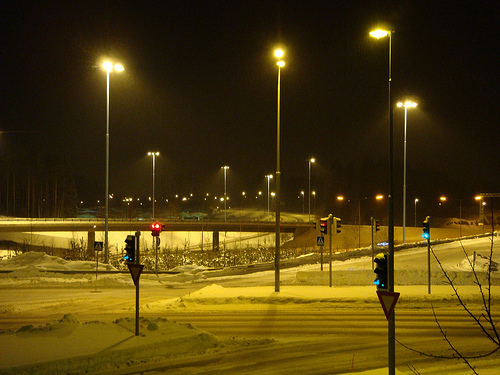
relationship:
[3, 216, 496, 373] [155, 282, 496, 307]
street covered in snow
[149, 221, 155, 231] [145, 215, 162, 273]
light on pole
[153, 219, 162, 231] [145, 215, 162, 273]
light on pole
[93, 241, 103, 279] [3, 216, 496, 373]
sign on street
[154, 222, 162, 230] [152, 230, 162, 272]
light on pole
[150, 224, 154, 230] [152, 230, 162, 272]
light on pole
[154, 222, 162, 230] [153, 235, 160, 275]
light on pole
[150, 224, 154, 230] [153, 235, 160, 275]
light on pole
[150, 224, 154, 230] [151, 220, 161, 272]
light on pole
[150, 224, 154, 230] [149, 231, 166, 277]
light on pole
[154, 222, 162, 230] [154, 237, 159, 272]
light on pole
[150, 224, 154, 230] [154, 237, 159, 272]
light on pole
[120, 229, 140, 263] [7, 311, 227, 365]
signal in snow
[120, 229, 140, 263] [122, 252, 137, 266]
signal with light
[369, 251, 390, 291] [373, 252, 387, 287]
signal with greenlight signal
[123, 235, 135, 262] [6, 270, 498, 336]
greenlight signal on side of street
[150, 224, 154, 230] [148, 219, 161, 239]
light has light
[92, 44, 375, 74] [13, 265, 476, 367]
lamp near road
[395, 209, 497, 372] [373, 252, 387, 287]
twig branches near greenlight signal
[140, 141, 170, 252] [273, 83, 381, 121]
light pole in ground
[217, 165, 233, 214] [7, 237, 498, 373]
pole in ground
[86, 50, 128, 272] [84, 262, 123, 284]
pole in ground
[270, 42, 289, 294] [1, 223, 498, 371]
light pole in ground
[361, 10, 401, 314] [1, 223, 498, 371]
pole in ground